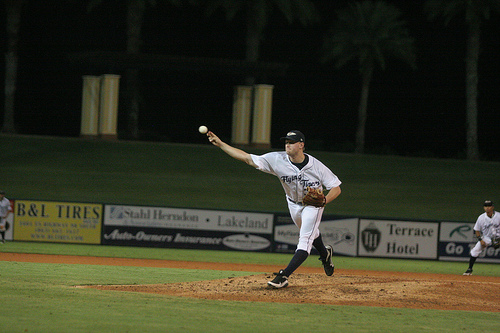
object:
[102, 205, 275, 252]
sign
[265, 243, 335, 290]
cleats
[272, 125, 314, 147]
hat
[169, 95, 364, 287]
man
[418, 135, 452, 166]
ground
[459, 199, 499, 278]
infielder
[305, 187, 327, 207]
glove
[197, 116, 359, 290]
baseman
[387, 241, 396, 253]
capital letter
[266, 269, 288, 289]
shoe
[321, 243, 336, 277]
shoe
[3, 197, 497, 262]
wall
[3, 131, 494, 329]
baseball field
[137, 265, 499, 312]
pitcher's mound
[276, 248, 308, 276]
sock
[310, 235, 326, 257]
sock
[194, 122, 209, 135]
ball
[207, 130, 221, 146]
hand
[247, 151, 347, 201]
shirt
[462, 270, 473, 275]
shoe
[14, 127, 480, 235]
hill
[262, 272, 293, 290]
cleat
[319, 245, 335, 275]
cleat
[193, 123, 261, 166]
pitch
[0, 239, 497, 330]
field